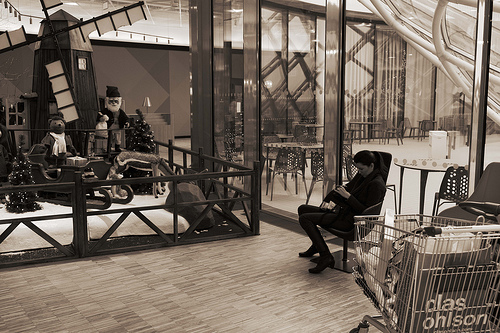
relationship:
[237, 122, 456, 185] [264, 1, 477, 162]
tables behind glass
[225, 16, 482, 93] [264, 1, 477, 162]
reflection seen in glass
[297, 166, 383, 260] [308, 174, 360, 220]
woman holds bag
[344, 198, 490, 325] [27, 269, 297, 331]
trolley on floor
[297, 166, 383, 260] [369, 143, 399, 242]
woman sits in chair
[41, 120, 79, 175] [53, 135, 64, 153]
bear wears scarf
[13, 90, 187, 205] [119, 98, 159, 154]
trees for christmas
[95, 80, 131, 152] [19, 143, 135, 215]
santa has sleigh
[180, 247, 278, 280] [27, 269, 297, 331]
line on floor